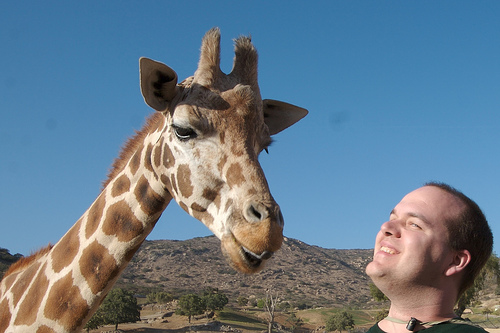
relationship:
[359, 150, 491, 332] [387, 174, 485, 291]
man has head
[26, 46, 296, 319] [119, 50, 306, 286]
giraffe has head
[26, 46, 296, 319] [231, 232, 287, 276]
giraffe has mouth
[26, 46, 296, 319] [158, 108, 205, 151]
giraffe has eye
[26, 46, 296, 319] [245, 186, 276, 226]
giraffe has nostril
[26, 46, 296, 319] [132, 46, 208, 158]
giraffe has ear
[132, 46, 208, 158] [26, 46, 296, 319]
ear on giraffe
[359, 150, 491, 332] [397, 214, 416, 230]
man has eye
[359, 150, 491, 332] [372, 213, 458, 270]
man has nose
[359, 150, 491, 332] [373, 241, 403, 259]
man has mouth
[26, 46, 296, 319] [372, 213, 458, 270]
giraffe has nose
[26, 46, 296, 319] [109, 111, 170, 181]
giraffe has mane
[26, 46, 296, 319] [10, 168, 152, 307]
giraffe has neck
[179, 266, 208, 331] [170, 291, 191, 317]
tree has leaves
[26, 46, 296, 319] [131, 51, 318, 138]
giraffe has ears